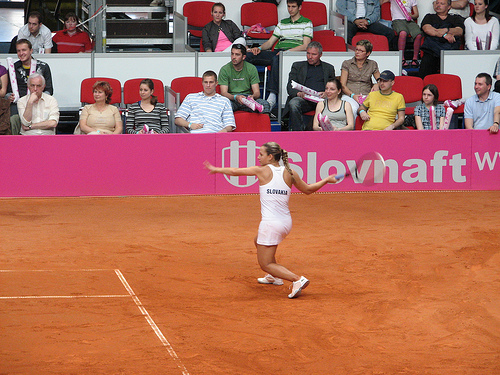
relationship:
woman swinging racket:
[197, 136, 348, 305] [333, 148, 390, 187]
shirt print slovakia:
[253, 161, 293, 215] [266, 186, 290, 195]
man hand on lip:
[11, 69, 64, 138] [31, 90, 41, 96]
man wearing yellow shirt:
[357, 66, 408, 131] [356, 89, 409, 134]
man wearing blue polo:
[459, 70, 496, 133] [463, 90, 499, 131]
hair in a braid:
[252, 135, 297, 181] [281, 146, 297, 181]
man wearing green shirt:
[216, 40, 268, 117] [217, 63, 262, 98]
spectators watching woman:
[5, 1, 499, 128] [197, 136, 348, 305]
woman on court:
[197, 136, 348, 305] [4, 195, 498, 374]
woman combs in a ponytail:
[197, 136, 348, 305] [281, 146, 297, 181]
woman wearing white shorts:
[197, 136, 348, 305] [252, 215, 297, 251]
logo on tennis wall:
[287, 143, 472, 192] [283, 134, 495, 188]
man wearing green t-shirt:
[216, 40, 268, 117] [217, 63, 262, 98]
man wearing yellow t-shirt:
[357, 66, 408, 131] [356, 89, 409, 134]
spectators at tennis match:
[5, 1, 499, 128] [197, 136, 348, 305]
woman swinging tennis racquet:
[197, 136, 348, 305] [333, 148, 390, 187]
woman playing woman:
[197, 136, 348, 305] [197, 136, 348, 305]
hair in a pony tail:
[252, 135, 297, 181] [276, 141, 295, 174]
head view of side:
[252, 135, 297, 181] [257, 146, 274, 163]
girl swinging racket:
[197, 136, 348, 305] [333, 148, 390, 187]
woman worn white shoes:
[197, 136, 348, 305] [254, 271, 311, 302]